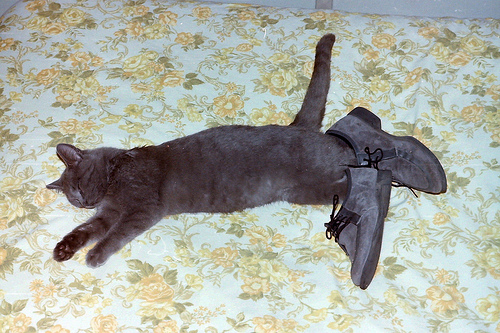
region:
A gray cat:
[43, 118, 273, 273]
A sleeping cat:
[41, 129, 290, 270]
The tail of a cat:
[301, 26, 342, 124]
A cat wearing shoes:
[43, 98, 464, 293]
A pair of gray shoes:
[328, 98, 453, 287]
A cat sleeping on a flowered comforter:
[38, 102, 310, 295]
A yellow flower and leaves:
[106, 46, 201, 98]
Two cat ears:
[33, 136, 87, 197]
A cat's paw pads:
[50, 234, 80, 266]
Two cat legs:
[38, 208, 175, 273]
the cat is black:
[108, 129, 375, 279]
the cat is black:
[147, 103, 313, 313]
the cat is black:
[75, 23, 283, 218]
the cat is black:
[109, 71, 244, 298]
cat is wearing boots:
[271, 70, 425, 322]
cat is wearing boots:
[361, 162, 484, 291]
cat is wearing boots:
[276, 94, 375, 261]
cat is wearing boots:
[307, 64, 407, 250]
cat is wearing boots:
[122, 70, 444, 310]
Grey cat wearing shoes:
[46, 31, 448, 291]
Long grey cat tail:
[299, 32, 339, 126]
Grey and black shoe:
[325, 164, 400, 291]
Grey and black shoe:
[323, 106, 448, 200]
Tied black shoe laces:
[321, 191, 351, 238]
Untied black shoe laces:
[363, 145, 420, 204]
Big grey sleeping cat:
[47, 32, 354, 269]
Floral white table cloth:
[1, 0, 496, 332]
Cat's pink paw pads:
[55, 245, 72, 260]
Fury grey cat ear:
[54, 142, 81, 168]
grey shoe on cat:
[331, 162, 389, 277]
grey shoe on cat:
[338, 105, 442, 185]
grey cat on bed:
[13, 33, 423, 265]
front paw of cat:
[64, 238, 144, 284]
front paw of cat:
[48, 237, 84, 261]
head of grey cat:
[40, 140, 110, 206]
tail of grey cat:
[286, 20, 344, 125]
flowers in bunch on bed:
[130, 257, 176, 304]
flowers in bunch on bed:
[241, 275, 273, 302]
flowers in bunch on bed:
[406, 260, 461, 315]